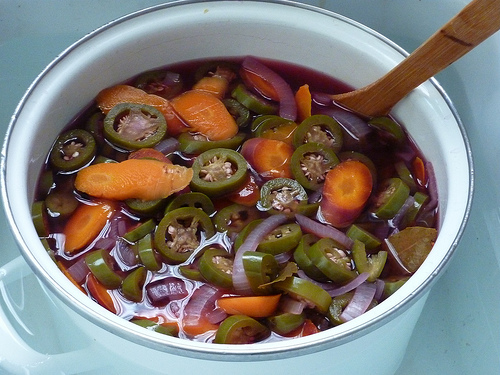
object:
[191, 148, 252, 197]
pepper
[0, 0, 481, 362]
pot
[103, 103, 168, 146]
pepper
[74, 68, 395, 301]
soup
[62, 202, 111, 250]
carrot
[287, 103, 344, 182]
jalapeno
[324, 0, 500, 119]
spoon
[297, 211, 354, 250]
onions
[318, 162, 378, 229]
carrot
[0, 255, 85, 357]
handle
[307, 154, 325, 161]
seeds